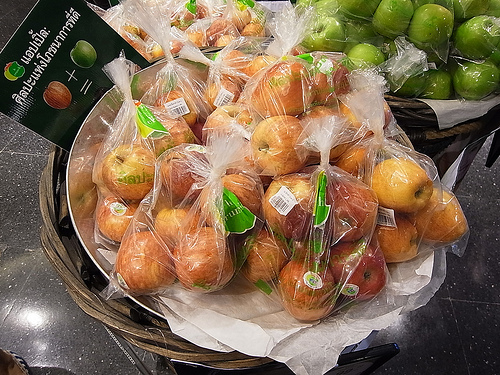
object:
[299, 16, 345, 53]
apple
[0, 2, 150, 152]
board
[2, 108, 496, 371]
floor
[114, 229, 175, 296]
apples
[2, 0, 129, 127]
book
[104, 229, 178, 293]
apples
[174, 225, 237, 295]
apples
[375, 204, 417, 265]
apples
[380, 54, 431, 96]
apples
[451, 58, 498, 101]
apples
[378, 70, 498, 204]
baskets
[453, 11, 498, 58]
green apple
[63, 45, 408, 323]
tray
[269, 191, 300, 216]
tag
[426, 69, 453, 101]
apple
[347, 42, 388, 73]
apple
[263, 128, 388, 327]
bag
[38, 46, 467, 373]
apples basket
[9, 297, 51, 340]
light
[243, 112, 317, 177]
apple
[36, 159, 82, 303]
edge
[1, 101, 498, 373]
table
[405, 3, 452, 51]
apple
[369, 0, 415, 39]
apple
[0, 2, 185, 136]
sign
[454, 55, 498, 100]
apple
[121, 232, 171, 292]
fruit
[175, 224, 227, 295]
fruit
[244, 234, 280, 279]
fruit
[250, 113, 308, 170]
fruit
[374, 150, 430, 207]
fruit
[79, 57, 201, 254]
bag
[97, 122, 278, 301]
bag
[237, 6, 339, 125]
bag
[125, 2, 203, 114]
bag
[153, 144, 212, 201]
fruits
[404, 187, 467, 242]
apple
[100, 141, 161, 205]
fruit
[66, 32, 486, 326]
apple sale